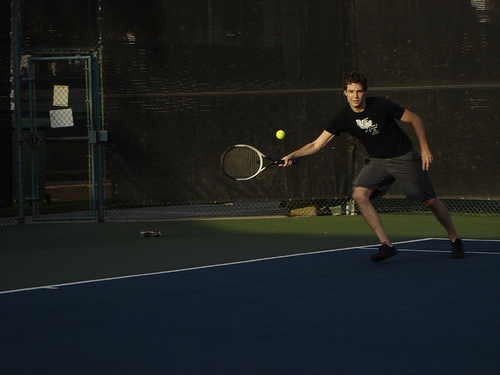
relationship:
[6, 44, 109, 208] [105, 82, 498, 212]
door side fence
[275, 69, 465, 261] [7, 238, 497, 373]
man on tennis court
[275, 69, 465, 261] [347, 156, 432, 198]
man wearing shorts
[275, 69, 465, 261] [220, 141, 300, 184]
man holding tennis racket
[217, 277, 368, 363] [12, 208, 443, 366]
blue color on court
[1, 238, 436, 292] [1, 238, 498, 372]
white line on court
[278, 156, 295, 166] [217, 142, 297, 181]
hand on racket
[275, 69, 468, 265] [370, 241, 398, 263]
man wearing shoes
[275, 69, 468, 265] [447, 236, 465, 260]
man wearing sneakers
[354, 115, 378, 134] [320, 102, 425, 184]
symbol on shirt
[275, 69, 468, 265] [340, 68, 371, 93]
man has short hair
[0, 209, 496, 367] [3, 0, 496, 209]
court has fence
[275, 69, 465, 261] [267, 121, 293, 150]
man hitting ball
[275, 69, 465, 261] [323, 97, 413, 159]
man wears shirt